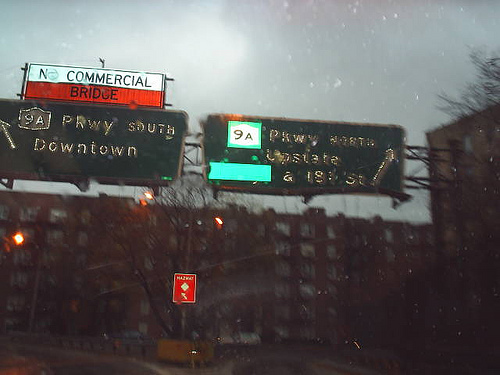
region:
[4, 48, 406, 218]
signs giving directions to drivers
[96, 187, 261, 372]
tree where the road diverges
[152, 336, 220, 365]
safety bumper where the road splits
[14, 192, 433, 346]
large housing units next to road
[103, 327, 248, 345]
cars parked next to aparments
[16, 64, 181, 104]
sign describing bridge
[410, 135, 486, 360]
metal post holding sign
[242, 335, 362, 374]
ramp of a diverging road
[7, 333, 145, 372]
ramp of diverging road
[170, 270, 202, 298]
red sign next to a leavless tree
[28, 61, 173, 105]
Sign that says no commercial bridge.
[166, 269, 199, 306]
Red sign with an arrow.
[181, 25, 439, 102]
It is raining in the picture.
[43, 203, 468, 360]
Part of the building.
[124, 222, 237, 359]
No leaves on the tree.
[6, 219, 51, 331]
Light shining on a pole.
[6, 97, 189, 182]
Large sign over interstate.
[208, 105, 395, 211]
Other large sign over interstate.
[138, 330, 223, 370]
Yellow part of the railing.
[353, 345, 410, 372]
Striped part of the railing.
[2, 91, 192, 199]
Sign of road is rectangular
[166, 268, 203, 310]
Red sign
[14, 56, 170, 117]
White and red sign on top of green sign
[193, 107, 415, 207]
Road sign has white letters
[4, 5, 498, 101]
Ski is cloudy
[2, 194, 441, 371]
Large red building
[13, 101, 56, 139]
9A is written on sign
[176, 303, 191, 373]
Pole that support red sign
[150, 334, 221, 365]
Yellow barricade on corner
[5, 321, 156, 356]
Rail on center of street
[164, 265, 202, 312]
red and white sign in street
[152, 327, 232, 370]
yellow barrier on corner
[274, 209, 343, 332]
city building with square windows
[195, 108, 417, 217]
sign suspended over road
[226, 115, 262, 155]
bright patch on sign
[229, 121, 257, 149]
number and letter in black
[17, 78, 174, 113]
orange bottom of sign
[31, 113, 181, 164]
white reflective letters on sign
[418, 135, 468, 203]
metal poles holding sign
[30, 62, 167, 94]
black lettering on white background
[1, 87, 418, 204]
she signs are black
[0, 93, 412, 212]
the signs are dirty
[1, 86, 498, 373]
the buildings are brick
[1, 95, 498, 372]
the buildings have windows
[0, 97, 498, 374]
the buildings are tall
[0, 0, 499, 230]
the sky is grey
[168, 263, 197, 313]
the sign is red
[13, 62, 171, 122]
the sign is orange and white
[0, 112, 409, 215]
the signs have arrows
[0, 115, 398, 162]
the arrows are white